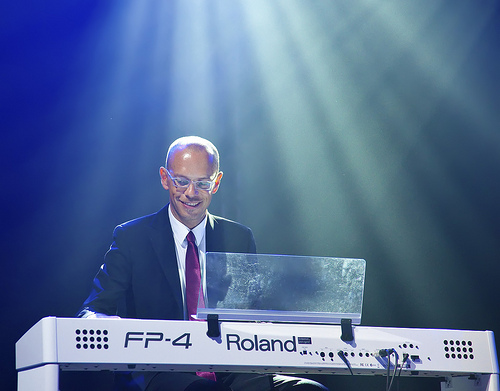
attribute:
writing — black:
[121, 330, 193, 349]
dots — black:
[442, 335, 478, 360]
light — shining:
[358, 190, 433, 248]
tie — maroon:
[183, 229, 211, 324]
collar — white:
[169, 209, 214, 247]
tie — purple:
[180, 230, 209, 320]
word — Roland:
[219, 329, 299, 362]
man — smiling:
[87, 137, 323, 388]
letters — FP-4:
[120, 319, 191, 360]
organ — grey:
[9, 313, 491, 388]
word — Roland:
[227, 330, 300, 359]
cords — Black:
[335, 347, 422, 374]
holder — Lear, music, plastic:
[192, 247, 369, 328]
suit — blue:
[86, 210, 326, 388]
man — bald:
[76, 135, 285, 314]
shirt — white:
[163, 211, 216, 311]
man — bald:
[79, 128, 274, 315]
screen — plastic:
[189, 244, 372, 337]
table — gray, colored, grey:
[10, 311, 499, 390]